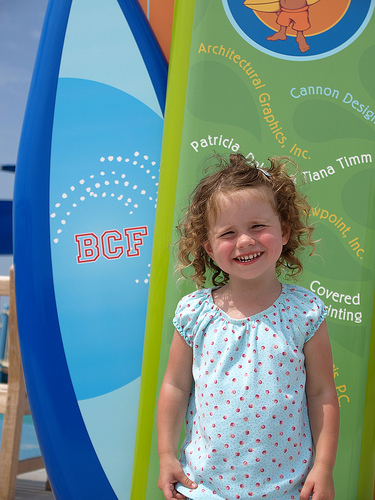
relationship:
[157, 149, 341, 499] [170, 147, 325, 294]
girl has hair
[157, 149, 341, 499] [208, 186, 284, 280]
girl has face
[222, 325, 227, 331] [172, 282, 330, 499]
dot decorates shirt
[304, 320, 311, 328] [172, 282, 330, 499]
dot decorates shirt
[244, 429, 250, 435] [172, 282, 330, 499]
dot decorates shirt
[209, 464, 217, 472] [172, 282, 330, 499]
dot decorates shirt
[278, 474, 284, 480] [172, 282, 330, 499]
dot decorates shirt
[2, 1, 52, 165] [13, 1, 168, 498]
sky visible behind surfboard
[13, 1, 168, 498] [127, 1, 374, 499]
surfboard leaning on surfboard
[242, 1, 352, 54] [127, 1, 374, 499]
character printed on surfboard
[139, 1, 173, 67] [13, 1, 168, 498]
surfboard behind surfboard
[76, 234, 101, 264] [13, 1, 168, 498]
letter printed on surfboard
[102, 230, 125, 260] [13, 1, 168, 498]
letter printed on surfboard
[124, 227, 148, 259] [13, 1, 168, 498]
letter printed on surfboard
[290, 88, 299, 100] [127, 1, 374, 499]
letter printed on surfboard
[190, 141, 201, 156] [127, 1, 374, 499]
letter printed on surfboard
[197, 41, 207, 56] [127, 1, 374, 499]
letter printed on surfboard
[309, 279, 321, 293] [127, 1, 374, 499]
letter printed on surfboard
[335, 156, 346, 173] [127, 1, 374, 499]
letter printed on surfboard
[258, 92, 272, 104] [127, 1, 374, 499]
letter printed on surfboard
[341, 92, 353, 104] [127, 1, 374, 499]
letter printed on surfboard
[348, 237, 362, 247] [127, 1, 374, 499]
letter printed on surfboard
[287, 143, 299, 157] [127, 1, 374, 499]
letter printed on surfboard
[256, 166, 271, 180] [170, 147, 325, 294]
ribbon worn in hair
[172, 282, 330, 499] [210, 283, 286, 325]
shirt has collar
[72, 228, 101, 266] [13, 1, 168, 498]
letter printed on surfboard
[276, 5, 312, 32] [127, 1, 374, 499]
shorts printed on surfboard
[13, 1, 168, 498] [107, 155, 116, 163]
surfboard has spot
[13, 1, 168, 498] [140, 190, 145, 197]
surfboard has spot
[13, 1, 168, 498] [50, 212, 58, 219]
surfboard has spot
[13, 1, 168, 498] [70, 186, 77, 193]
surfboard has spot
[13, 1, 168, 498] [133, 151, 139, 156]
surfboard has spot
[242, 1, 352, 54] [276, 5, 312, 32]
character wearing shorts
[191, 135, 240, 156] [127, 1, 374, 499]
patricia printed on surfboard